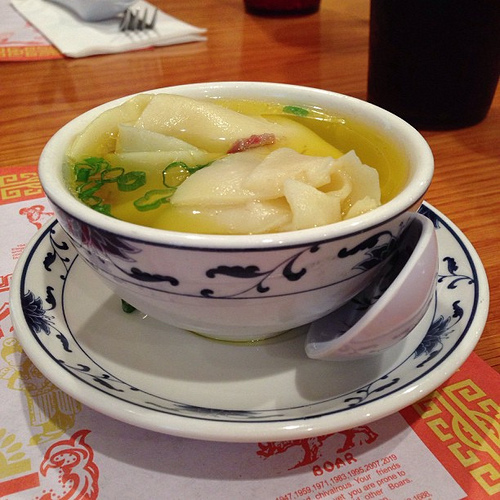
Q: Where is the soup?
A: On table.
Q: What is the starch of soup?
A: Noodle.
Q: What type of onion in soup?
A: Green.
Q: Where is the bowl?
A: On saucer.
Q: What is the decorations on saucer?
A: Flowers.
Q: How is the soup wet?
A: Liquid.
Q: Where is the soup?
A: In a bowl.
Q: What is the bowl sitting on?
A: A small plate.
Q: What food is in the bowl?
A: Soup.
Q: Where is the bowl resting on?
A: A saucer.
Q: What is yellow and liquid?
A: The soup.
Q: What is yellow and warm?
A: The soup.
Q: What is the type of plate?
A: China.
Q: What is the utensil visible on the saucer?
A: A spoon.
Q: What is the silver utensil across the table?
A: A fork.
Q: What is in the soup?
A: Wontons.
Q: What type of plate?
A: A bowl.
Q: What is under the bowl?
A: A plate.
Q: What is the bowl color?
A: Blue and white.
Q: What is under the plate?
A: A mat.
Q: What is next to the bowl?
A: A cup.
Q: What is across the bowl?
A: Utensils.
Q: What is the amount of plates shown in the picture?
A: Two.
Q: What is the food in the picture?
A: A bowl of soup.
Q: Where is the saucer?
A: Next to the bowl.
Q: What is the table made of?
A: Smooth brown wood.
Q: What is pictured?
A: Won ton soup.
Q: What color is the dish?
A: White and blue.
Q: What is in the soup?
A: Green onions.